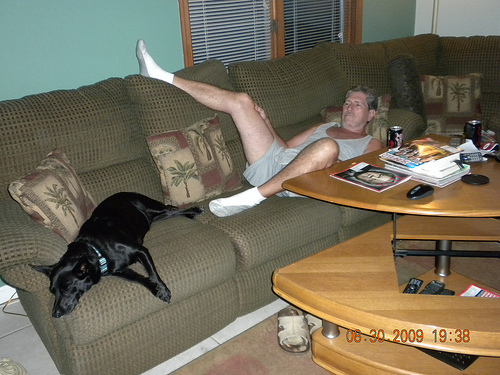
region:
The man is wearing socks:
[211, 185, 263, 216]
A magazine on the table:
[333, 162, 410, 191]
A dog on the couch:
[29, 190, 200, 320]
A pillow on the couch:
[145, 115, 243, 208]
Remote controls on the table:
[403, 278, 450, 296]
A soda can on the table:
[388, 127, 402, 147]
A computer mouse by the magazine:
[413, 182, 433, 199]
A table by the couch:
[273, 137, 499, 374]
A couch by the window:
[0, 35, 498, 374]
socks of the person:
[120, 40, 178, 93]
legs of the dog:
[124, 245, 190, 325]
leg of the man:
[191, 151, 280, 247]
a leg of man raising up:
[116, 38, 241, 160]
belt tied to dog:
[91, 234, 113, 272]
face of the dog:
[33, 251, 117, 334]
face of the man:
[328, 73, 375, 134]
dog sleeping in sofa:
[49, 255, 119, 325]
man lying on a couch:
[131, 40, 398, 222]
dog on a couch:
[28, 189, 208, 319]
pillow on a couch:
[144, 124, 251, 211]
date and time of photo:
[329, 315, 477, 352]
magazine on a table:
[337, 159, 400, 196]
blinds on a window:
[184, 0, 272, 67]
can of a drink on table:
[385, 122, 410, 155]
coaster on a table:
[461, 167, 492, 193]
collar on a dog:
[82, 236, 118, 277]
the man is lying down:
[125, 33, 483, 371]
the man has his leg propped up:
[112, 39, 399, 227]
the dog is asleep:
[34, 207, 181, 359]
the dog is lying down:
[23, 217, 215, 348]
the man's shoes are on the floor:
[259, 296, 370, 355]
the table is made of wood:
[302, 219, 397, 328]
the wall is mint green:
[21, 23, 113, 86]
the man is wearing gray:
[239, 84, 461, 331]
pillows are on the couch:
[30, 134, 431, 256]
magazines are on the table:
[366, 155, 477, 211]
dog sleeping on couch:
[43, 211, 210, 318]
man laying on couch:
[355, 152, 403, 199]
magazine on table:
[336, 155, 405, 202]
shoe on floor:
[270, 303, 338, 360]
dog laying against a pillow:
[10, 129, 188, 339]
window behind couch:
[172, 0, 407, 107]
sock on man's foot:
[208, 164, 299, 232]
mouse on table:
[402, 178, 450, 209]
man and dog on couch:
[26, 93, 462, 308]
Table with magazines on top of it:
[325, 105, 497, 217]